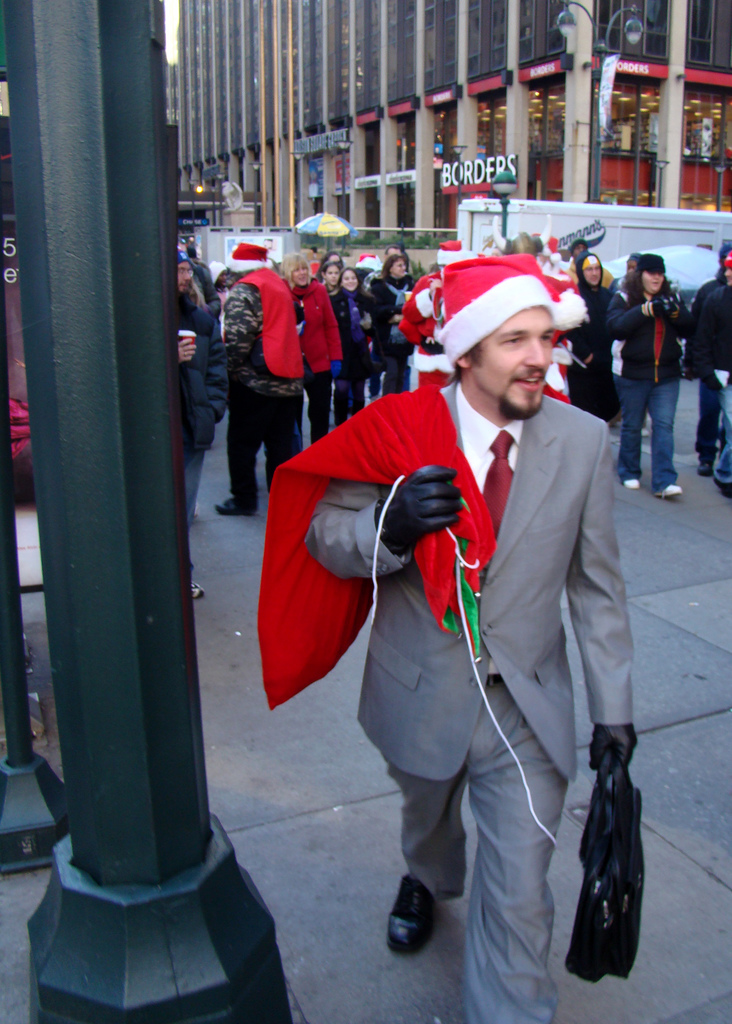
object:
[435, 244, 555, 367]
hat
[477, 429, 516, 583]
tie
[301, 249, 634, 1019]
man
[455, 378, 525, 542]
shirt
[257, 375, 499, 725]
bag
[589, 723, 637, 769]
glove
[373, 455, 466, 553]
glove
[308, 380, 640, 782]
jacket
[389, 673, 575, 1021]
pants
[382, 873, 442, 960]
shoe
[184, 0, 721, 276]
building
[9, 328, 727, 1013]
sidewalk